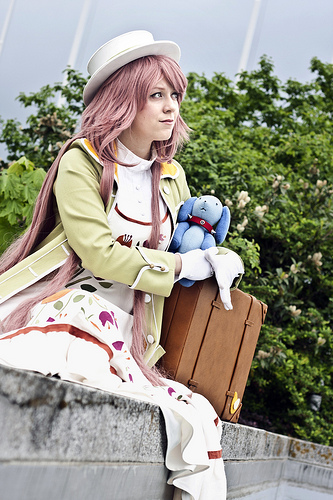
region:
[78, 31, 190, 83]
a white hat on a girl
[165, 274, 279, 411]
a brown leather suitcase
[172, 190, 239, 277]
a blue stuffed animal dog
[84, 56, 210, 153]
a girl with pink hair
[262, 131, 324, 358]
a section of trees in the background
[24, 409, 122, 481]
a section of a cement ledge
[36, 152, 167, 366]
a green coat over a white dress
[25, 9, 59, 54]
a section of the blue sky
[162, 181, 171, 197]
a white button on a green coat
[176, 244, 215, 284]
a white glove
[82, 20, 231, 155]
woman with pink hair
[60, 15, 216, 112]
womah wearing white hat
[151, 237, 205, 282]
woman wearing white gloves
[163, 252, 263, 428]
brown suitcase in photo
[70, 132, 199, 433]
woman in white dress with colors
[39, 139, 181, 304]
woman wearing greenish-colored jacket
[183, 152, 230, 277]
blue stuffed animal with red collar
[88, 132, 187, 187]
yellow collar on green jacket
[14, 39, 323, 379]
woman sitting in front of green bush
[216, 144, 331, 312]
white flowers on green bush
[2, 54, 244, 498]
Woman with pink hair sitting on a stone wall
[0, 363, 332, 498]
Stone wall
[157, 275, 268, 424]
Brown suitcase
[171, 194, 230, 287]
Blue stuffed animal with a red collar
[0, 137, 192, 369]
Beige coat with white buttons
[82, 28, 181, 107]
White hat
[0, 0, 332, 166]
Blue sky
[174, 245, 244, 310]
Pair of white gloves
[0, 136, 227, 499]
White dress worn by a woman with pink hair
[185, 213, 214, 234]
Red collar on a blue stuffed animal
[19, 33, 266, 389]
Woman with long pink hair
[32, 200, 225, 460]
White dress with pink flowers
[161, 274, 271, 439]
Tan suitcase next to girl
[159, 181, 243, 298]
Blue stuffed dog with red collar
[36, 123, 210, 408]
Green and white jacket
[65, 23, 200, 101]
White hat worn by woman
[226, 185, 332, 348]
White flowers on green bush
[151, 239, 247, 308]
White gloves worn by woman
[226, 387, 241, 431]
Little yellow piece on suitcase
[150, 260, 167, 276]
Buttons on cuff of jacket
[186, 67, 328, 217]
The bushes are green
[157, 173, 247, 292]
The woman is holding a stuffed animal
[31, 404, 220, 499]
The wall is gray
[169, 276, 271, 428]
The suit case is brown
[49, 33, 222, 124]
The woman is wearing a hat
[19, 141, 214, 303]
The woman has a green coat on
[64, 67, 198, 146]
The woman's eyes are open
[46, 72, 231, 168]
The woman has pink hair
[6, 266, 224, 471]
The woman's dress has many colors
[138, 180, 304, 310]
The stuffed animal is blue